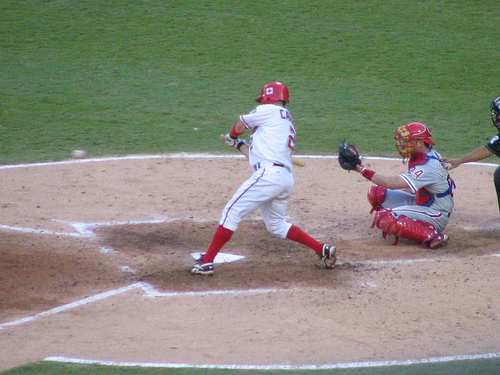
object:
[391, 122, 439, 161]
head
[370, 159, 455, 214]
jersey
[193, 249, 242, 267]
plate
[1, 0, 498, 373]
ground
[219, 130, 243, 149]
hands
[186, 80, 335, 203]
batter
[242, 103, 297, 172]
jersey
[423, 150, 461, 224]
back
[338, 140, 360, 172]
hand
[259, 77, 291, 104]
batters head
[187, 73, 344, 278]
man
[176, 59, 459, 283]
baseball players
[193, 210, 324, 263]
socks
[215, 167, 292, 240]
pants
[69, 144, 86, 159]
baseball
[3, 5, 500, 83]
ground is grass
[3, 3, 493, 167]
grass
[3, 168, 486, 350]
ground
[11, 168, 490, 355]
dirt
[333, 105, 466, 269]
catcher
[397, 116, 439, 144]
helmet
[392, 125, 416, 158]
mask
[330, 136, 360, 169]
mitt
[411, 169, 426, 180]
4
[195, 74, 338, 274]
batter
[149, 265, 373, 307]
lines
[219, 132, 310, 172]
bat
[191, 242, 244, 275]
base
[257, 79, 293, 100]
helmet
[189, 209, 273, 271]
right leg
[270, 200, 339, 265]
left leg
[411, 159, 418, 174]
number 2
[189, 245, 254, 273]
plate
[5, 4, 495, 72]
grass plain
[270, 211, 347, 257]
leg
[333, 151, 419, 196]
arm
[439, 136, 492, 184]
umpire's hand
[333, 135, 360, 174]
catcher's glove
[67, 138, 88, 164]
batter ball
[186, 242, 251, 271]
white plate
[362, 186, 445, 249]
leg guards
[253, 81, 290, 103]
red helmet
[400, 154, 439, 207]
red vest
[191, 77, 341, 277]
batter in uniform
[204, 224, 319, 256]
red socks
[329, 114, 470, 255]
catcher uniform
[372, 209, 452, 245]
safety pads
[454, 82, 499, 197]
baseball umpire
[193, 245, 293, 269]
home plate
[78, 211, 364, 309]
batter's box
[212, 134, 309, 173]
wooden bat